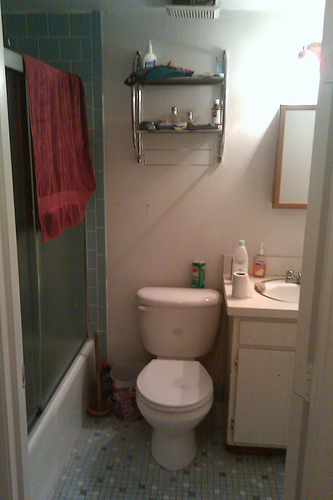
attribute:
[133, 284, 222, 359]
toilet tank — pictured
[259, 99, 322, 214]
mirror — wood-framed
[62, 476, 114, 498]
tiles — small, square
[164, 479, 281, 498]
tiles — small, square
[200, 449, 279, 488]
tiles — small, square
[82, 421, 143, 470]
tiles — small, square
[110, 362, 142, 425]
trash can — small, round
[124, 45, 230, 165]
shelf — silver, metal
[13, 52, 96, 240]
towel — red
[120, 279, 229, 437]
seat — toilet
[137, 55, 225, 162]
shelves — metal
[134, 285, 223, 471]
toilet — white, plastic, pictured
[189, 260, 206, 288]
comet cleanser — can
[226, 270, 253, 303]
roll — toilet paper, used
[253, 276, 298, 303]
sink — metal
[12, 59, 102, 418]
shower door — frosted glass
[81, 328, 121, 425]
plunger — toilet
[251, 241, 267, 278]
shampoo — bottle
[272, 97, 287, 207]
frame — wood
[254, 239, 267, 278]
hand soap — pictured